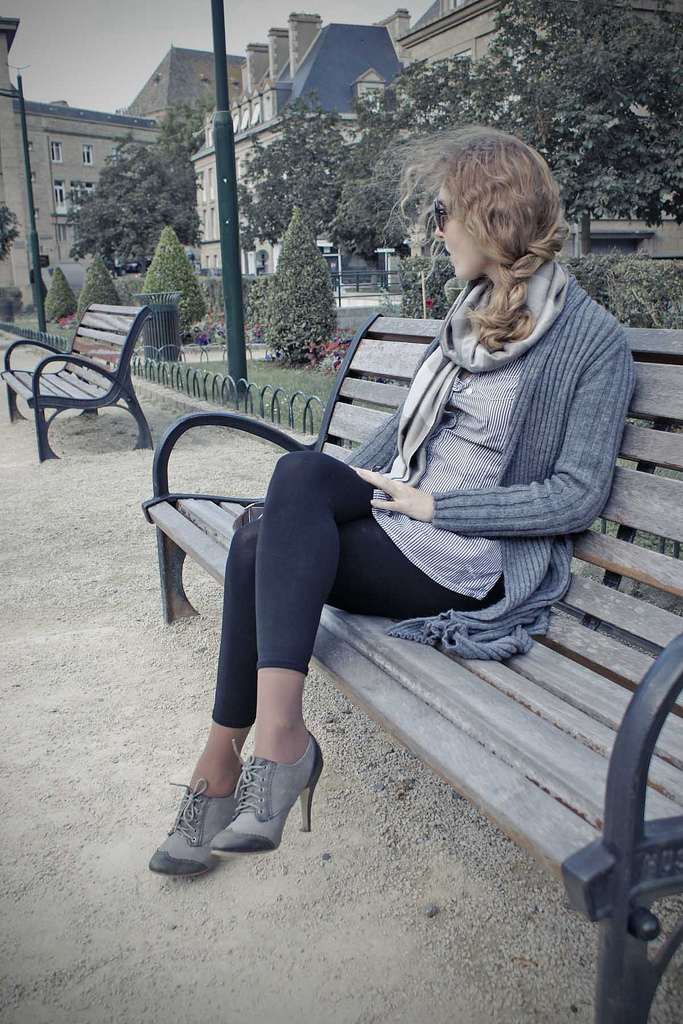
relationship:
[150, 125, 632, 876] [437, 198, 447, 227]
woman wearing glasses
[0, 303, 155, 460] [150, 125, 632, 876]
bench next to woman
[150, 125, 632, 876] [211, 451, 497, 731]
woman wearing black leggings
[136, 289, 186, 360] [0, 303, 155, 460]
black trashcan behind bench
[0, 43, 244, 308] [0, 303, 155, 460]
building behind bench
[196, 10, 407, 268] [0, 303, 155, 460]
building behind bench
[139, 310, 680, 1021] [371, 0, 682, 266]
bench behind building